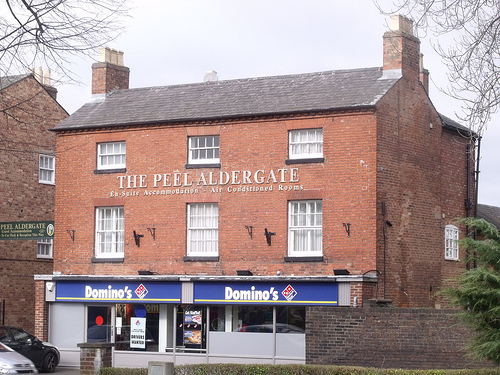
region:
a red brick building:
[342, 140, 437, 212]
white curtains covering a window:
[276, 194, 336, 254]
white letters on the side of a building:
[108, 162, 311, 193]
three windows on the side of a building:
[83, 190, 336, 277]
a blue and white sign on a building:
[53, 275, 346, 315]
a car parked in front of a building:
[1, 309, 77, 358]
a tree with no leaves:
[450, 6, 487, 138]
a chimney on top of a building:
[93, 27, 143, 93]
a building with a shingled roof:
[244, 45, 392, 233]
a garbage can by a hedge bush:
[134, 352, 179, 372]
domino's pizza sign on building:
[49, 273, 348, 308]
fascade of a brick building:
[334, 133, 370, 185]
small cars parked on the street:
[0, 323, 73, 374]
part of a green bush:
[449, 217, 499, 322]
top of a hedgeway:
[186, 365, 336, 374]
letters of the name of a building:
[110, 168, 316, 191]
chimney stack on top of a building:
[380, 8, 422, 80]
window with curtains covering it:
[276, 123, 333, 163]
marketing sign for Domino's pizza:
[176, 310, 206, 346]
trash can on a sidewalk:
[140, 359, 173, 374]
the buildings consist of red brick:
[8, 5, 496, 368]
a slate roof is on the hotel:
[49, 66, 391, 130]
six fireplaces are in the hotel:
[83, 15, 420, 73]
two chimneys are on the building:
[68, 35, 423, 105]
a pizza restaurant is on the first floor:
[31, 267, 361, 368]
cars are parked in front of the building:
[4, 238, 145, 367]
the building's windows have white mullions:
[33, 128, 461, 268]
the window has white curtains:
[183, 201, 221, 258]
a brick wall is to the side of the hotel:
[304, 298, 496, 368]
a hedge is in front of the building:
[102, 356, 497, 373]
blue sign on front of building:
[208, 274, 318, 310]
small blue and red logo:
[280, 285, 305, 304]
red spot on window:
[88, 310, 113, 336]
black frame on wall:
[256, 222, 286, 247]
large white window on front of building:
[280, 197, 335, 262]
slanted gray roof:
[182, 95, 275, 118]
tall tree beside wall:
[450, 217, 497, 301]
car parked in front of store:
[6, 323, 70, 368]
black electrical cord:
[379, 208, 401, 305]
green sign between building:
[4, 207, 81, 251]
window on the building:
[78, 141, 150, 176]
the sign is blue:
[34, 265, 361, 329]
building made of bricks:
[61, 62, 428, 313]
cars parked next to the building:
[1, 303, 79, 373]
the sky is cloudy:
[137, 3, 358, 81]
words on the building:
[101, 166, 331, 210]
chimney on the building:
[67, 29, 209, 161]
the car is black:
[1, 305, 81, 369]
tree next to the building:
[424, 209, 495, 371]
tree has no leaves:
[392, 2, 497, 117]